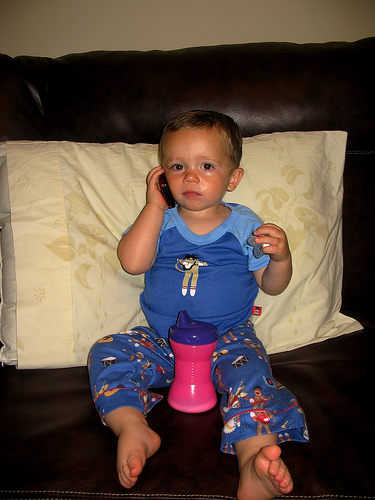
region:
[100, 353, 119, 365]
picture on child's pajamas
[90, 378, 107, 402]
picture on child's pajamas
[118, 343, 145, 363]
picture on child's pajamas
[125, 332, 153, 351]
picture on child's pajamas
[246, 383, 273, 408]
picture on child's pajamas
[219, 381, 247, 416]
picture on child's pajamas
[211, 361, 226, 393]
picture on child's pajamas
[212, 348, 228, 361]
picture on child's pajamas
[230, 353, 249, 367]
picture on child's pajamas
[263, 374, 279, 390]
picture on child's pajamas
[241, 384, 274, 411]
picture on baby pajama's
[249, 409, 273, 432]
picture on baby pajama's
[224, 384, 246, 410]
picture on baby pajama's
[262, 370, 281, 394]
picture on baby pajama's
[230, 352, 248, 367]
picture on baby pajama's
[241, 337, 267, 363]
picture on baby pajama's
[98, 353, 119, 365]
picture on baby pajama's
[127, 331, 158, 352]
picture on baby pajama's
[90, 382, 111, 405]
picture on child's pajamas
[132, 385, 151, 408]
picture on child's pajamas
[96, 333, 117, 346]
picture on child's pajamas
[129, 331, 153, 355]
picture on child's pajamas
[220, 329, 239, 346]
picture on child's pajamas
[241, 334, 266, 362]
picture on child's pajamas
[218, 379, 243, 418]
picture on child's pajamas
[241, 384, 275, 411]
picture on child's pajamas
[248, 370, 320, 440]
Pink and blue sippy cup on the bed.Pink and blue sippy cup on the bed.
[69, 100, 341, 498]
little boy on the phone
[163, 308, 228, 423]
pink and purple cup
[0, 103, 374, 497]
little boy leaning on a pillow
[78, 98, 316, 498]
little boy with blonde hair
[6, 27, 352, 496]
little boy on a couch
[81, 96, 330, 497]
little boy wearing a blue shirt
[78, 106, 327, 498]
little boy wearing blue pants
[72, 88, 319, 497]
little boy holding a phone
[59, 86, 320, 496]
little boy with no socks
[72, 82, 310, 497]
little boy with cup between his legs